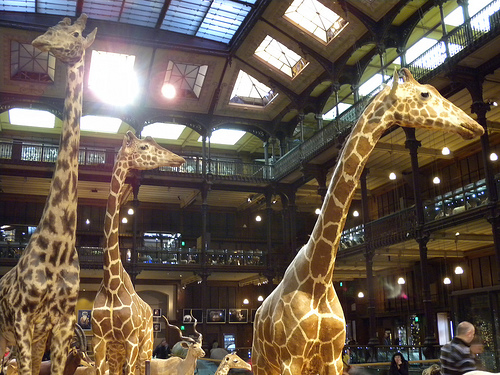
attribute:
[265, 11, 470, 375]
giraffe — pictured, standing, lifesize, tall, yellow, statue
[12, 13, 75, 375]
statue — brown, shiny, giraffe, standing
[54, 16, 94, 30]
horns — sharp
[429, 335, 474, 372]
shirt — striped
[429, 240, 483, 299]
lights — hanging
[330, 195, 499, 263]
railing — black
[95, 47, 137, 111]
sunlight — coming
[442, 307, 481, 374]
man — walking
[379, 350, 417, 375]
woman — sitting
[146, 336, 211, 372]
deer — standing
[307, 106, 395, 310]
neck — tall